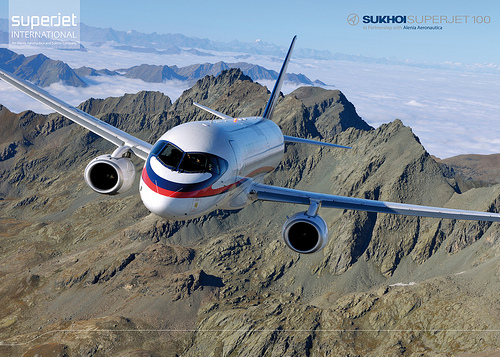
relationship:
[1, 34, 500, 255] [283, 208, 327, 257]
airplane has engine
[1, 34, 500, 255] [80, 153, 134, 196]
airplane has engine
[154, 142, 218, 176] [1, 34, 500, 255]
window on front of airplane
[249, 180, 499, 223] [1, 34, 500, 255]
wing on side of airplane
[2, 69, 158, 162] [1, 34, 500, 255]
wing on side of airplane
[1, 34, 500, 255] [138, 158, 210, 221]
airplane has nose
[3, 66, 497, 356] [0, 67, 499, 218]
mountain in distance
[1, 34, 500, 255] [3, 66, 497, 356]
airplane flying over mountain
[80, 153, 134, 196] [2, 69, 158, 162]
engine on wing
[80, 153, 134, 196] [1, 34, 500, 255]
engine on airplane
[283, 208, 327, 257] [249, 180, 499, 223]
engine on wing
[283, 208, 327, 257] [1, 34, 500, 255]
engine on airplane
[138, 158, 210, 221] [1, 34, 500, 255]
nose in front of airplane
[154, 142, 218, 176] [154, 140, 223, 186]
window on cockpit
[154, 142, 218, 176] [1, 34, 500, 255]
window on airplane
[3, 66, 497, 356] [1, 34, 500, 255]
mountain behind airplane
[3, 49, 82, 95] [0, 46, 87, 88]
mountain has mountain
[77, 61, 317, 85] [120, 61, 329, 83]
mountain has mountain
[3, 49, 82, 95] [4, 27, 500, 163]
mountain showing through clouds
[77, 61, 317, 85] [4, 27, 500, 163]
mountain showing through clouds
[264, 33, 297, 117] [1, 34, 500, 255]
tail on back of airplane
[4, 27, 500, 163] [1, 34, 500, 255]
clouds are behind airplane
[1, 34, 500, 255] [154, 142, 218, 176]
airplane has window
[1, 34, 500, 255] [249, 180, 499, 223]
airplane has wing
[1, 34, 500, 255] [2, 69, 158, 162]
airplane has wing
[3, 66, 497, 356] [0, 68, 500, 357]
mountain has mountain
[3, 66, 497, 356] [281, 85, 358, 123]
mountain has peak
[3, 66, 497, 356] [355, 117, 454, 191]
mountain has peak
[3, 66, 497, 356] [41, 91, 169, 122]
mountain has peak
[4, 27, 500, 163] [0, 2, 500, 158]
clouds are in sky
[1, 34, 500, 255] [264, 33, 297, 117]
airplane has tail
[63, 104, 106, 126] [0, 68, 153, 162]
logo on wing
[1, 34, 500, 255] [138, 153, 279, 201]
airplane has stripes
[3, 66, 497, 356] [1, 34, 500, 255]
mountain are below airplane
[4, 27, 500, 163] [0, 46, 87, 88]
clouds are meeting mountain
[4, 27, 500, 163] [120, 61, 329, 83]
clouds are meeting mountain